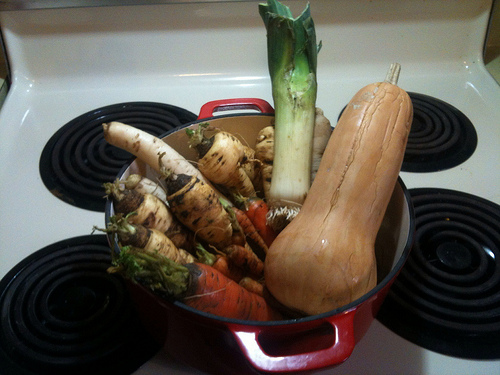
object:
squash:
[261, 63, 416, 318]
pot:
[104, 98, 416, 374]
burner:
[386, 186, 499, 357]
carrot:
[107, 245, 287, 323]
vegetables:
[253, 0, 323, 227]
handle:
[228, 310, 360, 374]